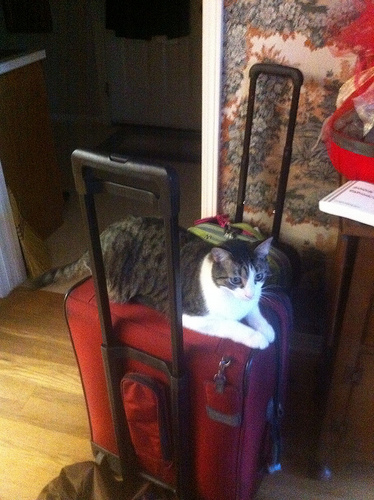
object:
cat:
[25, 215, 277, 350]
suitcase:
[185, 62, 305, 303]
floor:
[1, 285, 373, 498]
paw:
[244, 331, 269, 350]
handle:
[70, 146, 195, 498]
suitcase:
[63, 146, 294, 493]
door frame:
[202, 0, 223, 218]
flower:
[223, 25, 252, 94]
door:
[1, 1, 222, 303]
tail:
[29, 248, 90, 291]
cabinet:
[0, 48, 66, 242]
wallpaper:
[218, 1, 374, 339]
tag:
[193, 212, 231, 228]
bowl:
[324, 125, 374, 181]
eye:
[231, 277, 242, 285]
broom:
[6, 184, 53, 280]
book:
[318, 180, 374, 227]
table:
[309, 178, 374, 474]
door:
[104, 0, 201, 129]